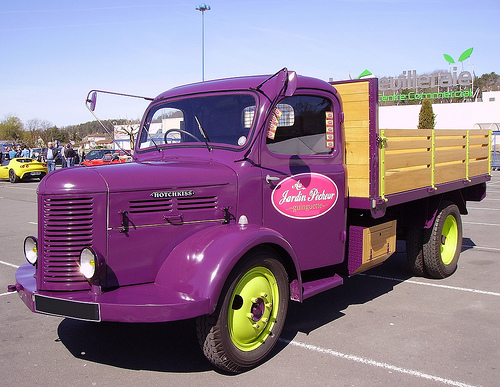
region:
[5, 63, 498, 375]
A PURPLE TRUCK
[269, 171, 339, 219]
A PINK AND WHITE LOGO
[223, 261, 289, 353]
YELLOW GREEN HUB CAP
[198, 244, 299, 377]
A BLACK TIRE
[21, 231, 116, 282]
TWO HEADLIGHTS ON A TRUCK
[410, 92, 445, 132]
A TREE IN THE DISTANCE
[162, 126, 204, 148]
A STEERING WHEEL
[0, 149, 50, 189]
A YELLOW SPORTS CAR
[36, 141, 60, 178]
A MAN STANDING NEAR A CAR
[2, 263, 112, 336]
A TRUCK FENDER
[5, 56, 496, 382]
The trunk has a purple coat of body paint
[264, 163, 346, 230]
Trunks logo on the door is pink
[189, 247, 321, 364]
Trunks wheel is lime yellow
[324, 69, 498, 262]
Trunks bed is light brown in color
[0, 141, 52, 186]
Car in background is yellow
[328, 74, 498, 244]
Trunks bed has a wooden texture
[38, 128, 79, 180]
People in the left of the background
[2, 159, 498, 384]
Trunk is in a parking lot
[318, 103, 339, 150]
Stickers on trunks side window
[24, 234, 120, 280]
Trunks headlight blubs are yellow in colored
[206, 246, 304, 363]
A tire with lemon green reams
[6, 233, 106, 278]
Two front lights with dark brims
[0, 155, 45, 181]
A yellow sports car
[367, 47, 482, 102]
A commercial sign with green highlights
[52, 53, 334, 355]
The front view of a purple truck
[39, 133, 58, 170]
A man staring at the truck from the distance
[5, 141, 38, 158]
A group of men gathering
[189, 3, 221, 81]
A tall street light with four lamps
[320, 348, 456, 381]
A white line of a parking space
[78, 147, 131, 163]
A red car with some decors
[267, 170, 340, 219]
Pink sign on truck.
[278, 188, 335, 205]
White letters on sign.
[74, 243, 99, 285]
Headlight on a truck.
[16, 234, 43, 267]
Headlight on a truck.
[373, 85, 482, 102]
Green letters on sign.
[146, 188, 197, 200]
Grey letters on truck.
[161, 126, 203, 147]
Steering wheel in truck.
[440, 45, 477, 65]
Green leaves on sign.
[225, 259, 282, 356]
Hub cap on truck.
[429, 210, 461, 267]
Hub cap on truck.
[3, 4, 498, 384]
A purple Hotchkiss truck.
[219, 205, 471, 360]
The truck has yellow hubcaps.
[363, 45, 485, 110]
Commercial advertising sign in the background.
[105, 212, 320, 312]
Truck has purple rounded fenders.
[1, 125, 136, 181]
People looking at cars in the background.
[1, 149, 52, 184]
A yellow car in the background.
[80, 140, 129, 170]
A red car in the background.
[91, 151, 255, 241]
The engine door of the truck.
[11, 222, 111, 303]
The truck has two headlights.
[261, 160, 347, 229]
A pink business sign on the door of the truck.